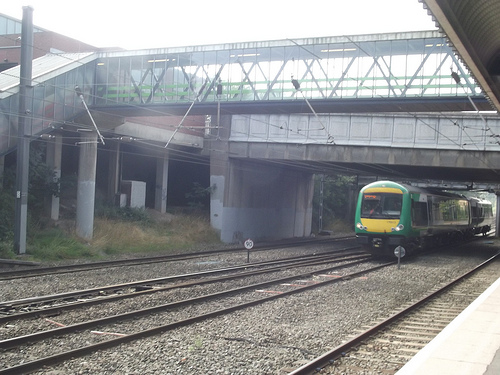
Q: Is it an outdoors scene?
A: Yes, it is outdoors.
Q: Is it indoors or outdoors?
A: It is outdoors.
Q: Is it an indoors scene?
A: No, it is outdoors.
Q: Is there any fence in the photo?
A: No, there are no fences.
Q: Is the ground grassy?
A: Yes, the ground is grassy.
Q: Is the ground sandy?
A: No, the ground is grassy.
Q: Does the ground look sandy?
A: No, the ground is grassy.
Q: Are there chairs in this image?
A: No, there are no chairs.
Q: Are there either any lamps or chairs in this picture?
A: No, there are no chairs or lamps.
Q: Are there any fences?
A: No, there are no fences.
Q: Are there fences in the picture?
A: No, there are no fences.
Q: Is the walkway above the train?
A: Yes, the walkway is above the train.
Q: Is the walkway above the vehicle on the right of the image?
A: Yes, the walkway is above the train.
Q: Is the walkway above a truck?
A: No, the walkway is above the train.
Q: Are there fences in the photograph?
A: No, there are no fences.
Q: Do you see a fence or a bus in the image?
A: No, there are no fences or buses.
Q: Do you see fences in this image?
A: No, there are no fences.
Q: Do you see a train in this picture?
A: Yes, there is a train.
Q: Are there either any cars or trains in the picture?
A: Yes, there is a train.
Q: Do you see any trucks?
A: No, there are no trucks.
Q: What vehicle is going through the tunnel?
A: The vehicle is a train.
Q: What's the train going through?
A: The train is going through the tunnel.